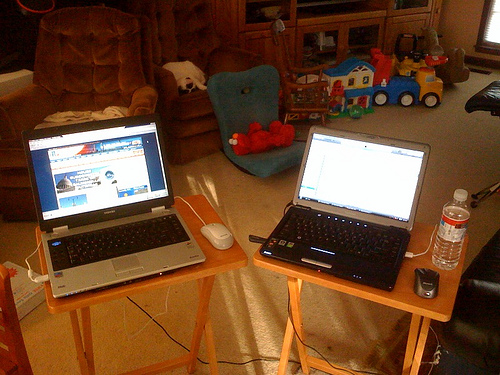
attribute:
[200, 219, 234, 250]
mouse — white, grey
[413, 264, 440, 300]
mouse — black, silver, wireless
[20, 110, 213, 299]
laptop — on, on the left, turned on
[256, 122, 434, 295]
laptop — on, on the right, turned on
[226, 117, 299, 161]
stuffed animal — red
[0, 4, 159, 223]
reclining chair — brown, stuffed, old, large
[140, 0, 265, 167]
recliner — stuffed, brown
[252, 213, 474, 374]
tv table — collapsible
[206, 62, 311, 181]
game chair — blue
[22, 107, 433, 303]
laptops — duo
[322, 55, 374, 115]
toy house — blue, white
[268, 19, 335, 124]
rocking chair — small, wooden